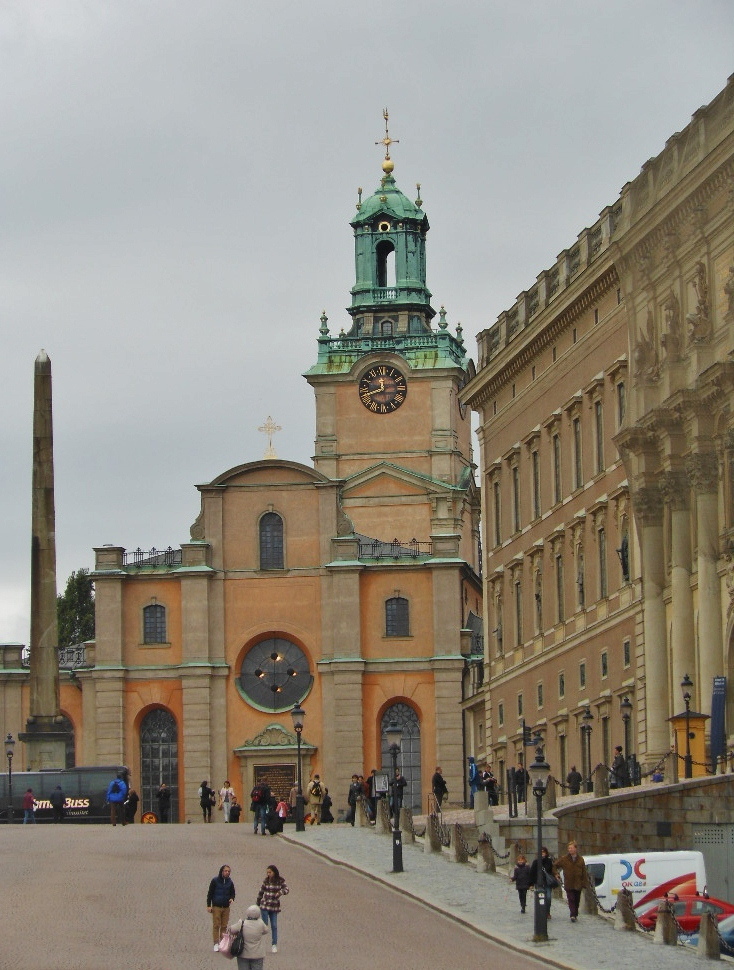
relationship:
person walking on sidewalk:
[552, 840, 587, 922] [284, 819, 691, 964]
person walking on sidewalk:
[529, 846, 553, 920] [284, 819, 691, 964]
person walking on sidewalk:
[509, 854, 531, 913] [284, 819, 691, 964]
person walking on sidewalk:
[552, 840, 587, 922] [277, 826, 733, 967]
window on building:
[386, 597, 410, 636] [72, 423, 464, 804]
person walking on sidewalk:
[256, 865, 288, 954] [284, 819, 691, 964]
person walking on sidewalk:
[207, 865, 236, 952] [284, 819, 691, 964]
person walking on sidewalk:
[350, 771, 363, 828] [284, 819, 691, 964]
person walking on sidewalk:
[557, 836, 590, 913] [277, 831, 676, 967]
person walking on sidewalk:
[532, 836, 557, 910] [277, 831, 676, 967]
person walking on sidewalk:
[509, 854, 531, 913] [277, 831, 676, 967]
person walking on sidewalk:
[428, 763, 450, 820] [277, 831, 676, 967]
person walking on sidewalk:
[392, 766, 410, 823] [277, 831, 676, 967]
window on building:
[143, 605, 166, 644] [19, 108, 480, 819]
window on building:
[386, 597, 410, 636] [1, 273, 488, 825]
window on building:
[386, 597, 410, 636] [19, 108, 480, 819]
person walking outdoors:
[204, 860, 238, 950] [1, 4, 712, 966]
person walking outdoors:
[225, 900, 271, 966] [1, 4, 712, 966]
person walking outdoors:
[256, 865, 288, 954] [1, 4, 712, 966]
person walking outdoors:
[509, 854, 531, 913] [1, 4, 712, 966]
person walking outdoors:
[552, 840, 587, 922] [1, 4, 712, 966]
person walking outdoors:
[505, 852, 537, 912] [1, 4, 712, 966]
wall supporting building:
[221, 469, 325, 819] [19, 108, 480, 819]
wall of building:
[206, 467, 395, 617] [210, 454, 348, 603]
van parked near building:
[560, 851, 706, 911] [453, 70, 702, 802]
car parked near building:
[635, 887, 712, 932] [453, 70, 702, 802]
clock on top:
[359, 365, 407, 415] [301, 106, 476, 376]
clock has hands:
[359, 365, 407, 415] [366, 359, 402, 395]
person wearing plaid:
[250, 853, 291, 886] [258, 876, 294, 905]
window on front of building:
[250, 505, 294, 574] [19, 108, 480, 819]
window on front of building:
[380, 589, 412, 639] [19, 108, 480, 819]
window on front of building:
[138, 599, 175, 656] [19, 108, 480, 819]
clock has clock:
[354, 359, 410, 415] [359, 365, 407, 415]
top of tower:
[299, 86, 464, 374] [307, 98, 507, 810]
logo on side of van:
[609, 854, 657, 884] [574, 842, 711, 915]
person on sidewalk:
[509, 854, 531, 913] [312, 826, 505, 942]